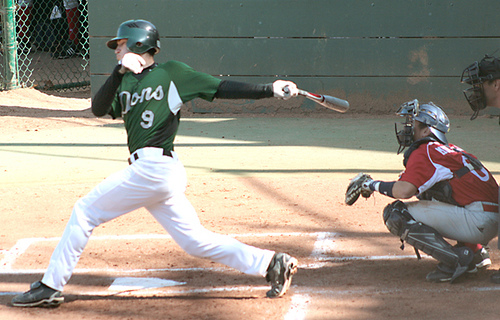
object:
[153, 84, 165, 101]
lettering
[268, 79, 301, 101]
hand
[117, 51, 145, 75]
hand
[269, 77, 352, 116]
holding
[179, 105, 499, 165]
shadows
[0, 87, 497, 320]
dirt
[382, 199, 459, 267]
shin guard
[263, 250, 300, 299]
baseball cleat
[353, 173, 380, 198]
hand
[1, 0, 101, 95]
fence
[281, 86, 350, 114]
bat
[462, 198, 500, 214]
belt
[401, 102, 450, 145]
helmet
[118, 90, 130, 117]
letters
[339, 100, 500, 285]
catcher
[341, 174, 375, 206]
mitt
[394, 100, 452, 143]
hat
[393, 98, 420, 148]
face mask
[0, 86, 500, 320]
field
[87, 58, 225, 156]
green shirt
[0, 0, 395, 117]
air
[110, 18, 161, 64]
head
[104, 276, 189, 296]
base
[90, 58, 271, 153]
top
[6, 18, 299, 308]
baseball player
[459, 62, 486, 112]
face mask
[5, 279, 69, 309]
cleat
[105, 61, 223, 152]
jersey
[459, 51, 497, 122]
umpire